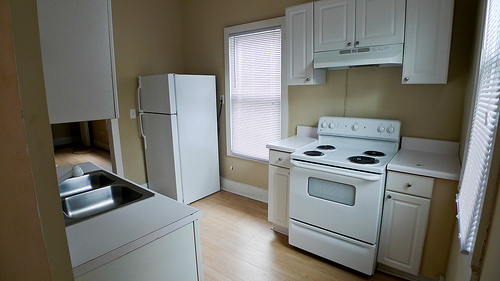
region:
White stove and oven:
[288, 72, 380, 262]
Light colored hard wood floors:
[215, 195, 260, 265]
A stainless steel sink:
[65, 150, 165, 206]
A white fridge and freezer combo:
[131, 55, 216, 197]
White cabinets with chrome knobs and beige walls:
[282, 8, 450, 102]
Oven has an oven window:
[292, 180, 357, 212]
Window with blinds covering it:
[216, 11, 286, 163]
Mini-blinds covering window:
[462, 21, 489, 257]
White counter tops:
[395, 130, 455, 176]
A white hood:
[310, 45, 400, 76]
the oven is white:
[296, 137, 381, 269]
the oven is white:
[326, 69, 357, 251]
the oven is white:
[318, 207, 343, 267]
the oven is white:
[296, 182, 353, 279]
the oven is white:
[328, 170, 375, 275]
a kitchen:
[33, 8, 485, 279]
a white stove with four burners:
[289, 112, 390, 268]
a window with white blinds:
[226, 28, 292, 151]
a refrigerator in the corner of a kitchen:
[136, 65, 234, 200]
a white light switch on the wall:
[126, 104, 141, 121]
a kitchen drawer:
[263, 146, 290, 171]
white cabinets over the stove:
[282, 0, 460, 43]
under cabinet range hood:
[311, 45, 406, 79]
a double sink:
[56, 163, 139, 218]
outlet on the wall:
[216, 91, 228, 116]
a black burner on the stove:
[343, 152, 378, 167]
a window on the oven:
[303, 173, 363, 211]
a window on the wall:
[222, 23, 289, 167]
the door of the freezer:
[134, 72, 179, 114]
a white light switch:
[126, 105, 138, 121]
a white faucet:
[58, 159, 88, 191]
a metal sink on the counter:
[58, 164, 155, 231]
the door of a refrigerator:
[133, 108, 189, 204]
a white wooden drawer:
[383, 167, 440, 199]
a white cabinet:
[372, 186, 434, 278]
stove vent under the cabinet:
[309, 42, 411, 79]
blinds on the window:
[208, 25, 301, 157]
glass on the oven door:
[296, 180, 380, 212]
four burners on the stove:
[313, 136, 388, 181]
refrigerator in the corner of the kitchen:
[138, 30, 238, 192]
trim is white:
[236, 173, 280, 205]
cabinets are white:
[282, 24, 392, 48]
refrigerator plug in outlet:
[217, 89, 228, 130]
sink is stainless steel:
[70, 170, 162, 215]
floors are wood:
[199, 231, 297, 279]